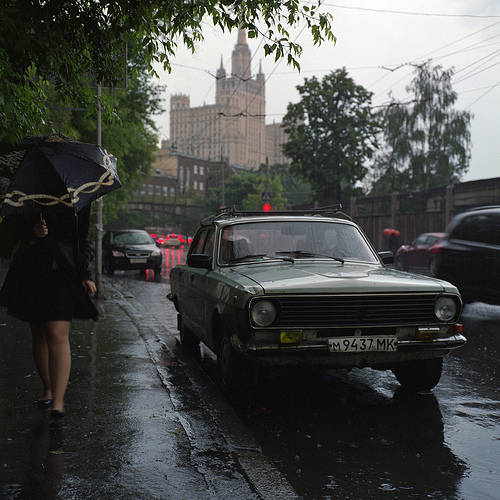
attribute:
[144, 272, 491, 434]
street — wet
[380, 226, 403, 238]
umbrella — red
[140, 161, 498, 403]
car — old 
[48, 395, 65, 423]
shoe — black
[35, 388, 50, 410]
shoe — black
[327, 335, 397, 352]
license plate — white, rectangular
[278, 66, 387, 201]
leaves — green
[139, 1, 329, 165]
building — tall, brown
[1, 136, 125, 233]
umbrella — black 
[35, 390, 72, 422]
flat shoes — black 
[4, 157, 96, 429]
lady — holding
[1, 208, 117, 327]
dress — black 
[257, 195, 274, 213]
traffic light — red